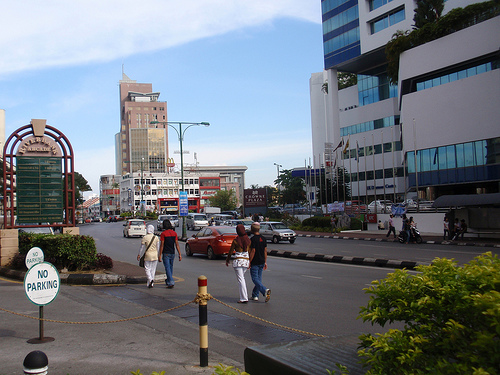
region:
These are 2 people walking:
[135, 222, 180, 288]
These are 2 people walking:
[231, 220, 263, 295]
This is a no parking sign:
[20, 260, 60, 300]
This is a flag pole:
[330, 135, 352, 207]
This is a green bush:
[386, 265, 491, 371]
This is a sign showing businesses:
[0, 120, 75, 225]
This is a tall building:
[120, 80, 165, 212]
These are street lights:
[145, 115, 207, 135]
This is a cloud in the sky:
[0, 7, 315, 18]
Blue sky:
[175, 28, 305, 113]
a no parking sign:
[23, 263, 58, 342]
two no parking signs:
[21, 246, 59, 343]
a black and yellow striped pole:
[195, 275, 210, 370]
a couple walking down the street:
[225, 221, 273, 303]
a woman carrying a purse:
[135, 224, 162, 289]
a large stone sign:
[0, 120, 76, 272]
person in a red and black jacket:
[158, 220, 183, 286]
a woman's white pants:
[237, 259, 252, 301]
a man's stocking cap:
[251, 221, 262, 231]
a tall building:
[117, 65, 170, 173]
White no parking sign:
[22, 263, 59, 305]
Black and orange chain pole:
[195, 274, 208, 366]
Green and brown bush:
[350, 249, 498, 374]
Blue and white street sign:
[179, 192, 188, 217]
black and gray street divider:
[259, 248, 424, 273]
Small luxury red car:
[182, 222, 237, 260]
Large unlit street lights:
[149, 121, 213, 241]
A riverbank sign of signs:
[1, 118, 76, 225]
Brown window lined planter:
[381, 1, 498, 43]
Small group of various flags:
[302, 140, 362, 175]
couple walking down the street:
[223, 220, 273, 303]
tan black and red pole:
[195, 270, 212, 373]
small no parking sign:
[23, 259, 60, 344]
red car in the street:
[182, 224, 240, 261]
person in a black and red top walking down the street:
[158, 219, 183, 293]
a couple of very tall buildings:
[120, 81, 170, 170]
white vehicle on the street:
[121, 219, 159, 236]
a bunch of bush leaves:
[359, 250, 498, 374]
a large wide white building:
[103, 177, 202, 214]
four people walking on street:
[145, 220, 296, 307]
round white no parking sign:
[11, 261, 62, 316]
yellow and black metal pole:
[185, 244, 226, 364]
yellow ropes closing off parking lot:
[7, 264, 428, 355]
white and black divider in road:
[265, 232, 446, 289]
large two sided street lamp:
[152, 105, 226, 270]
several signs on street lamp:
[165, 177, 199, 222]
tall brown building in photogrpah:
[95, 70, 199, 201]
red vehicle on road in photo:
[175, 214, 249, 285]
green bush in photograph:
[320, 247, 498, 371]